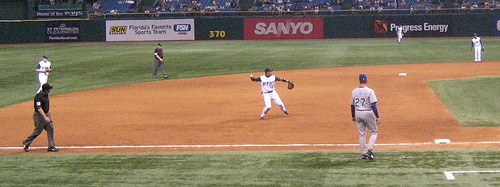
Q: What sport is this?
A: Baseball.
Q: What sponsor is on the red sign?
A: Sanyo.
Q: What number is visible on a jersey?
A: 27.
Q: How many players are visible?
A: 4.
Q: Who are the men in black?
A: Umpires.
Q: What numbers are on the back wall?
A: 370.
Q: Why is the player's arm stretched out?
A: Throwing the ball.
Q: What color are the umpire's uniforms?
A: Black.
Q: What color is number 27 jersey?
A: Gray.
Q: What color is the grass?
A: Green.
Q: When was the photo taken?
A: Yesterday.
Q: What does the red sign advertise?
A: Sanyo.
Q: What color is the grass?
A: Green.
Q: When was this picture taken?
A: Daytime.